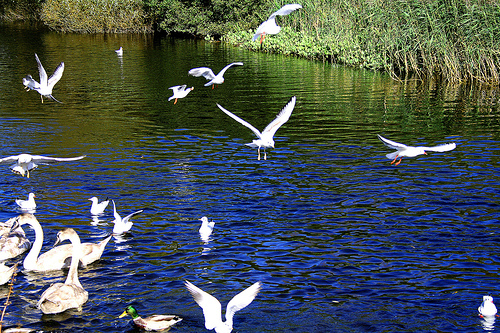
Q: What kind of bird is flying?
A: Seagull.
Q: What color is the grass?
A: Green.